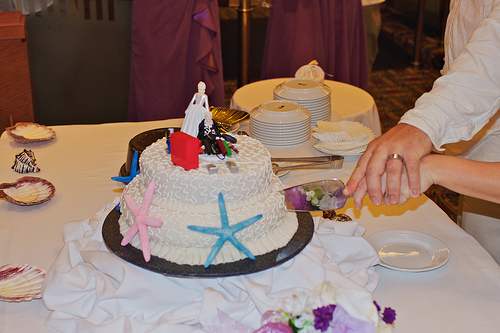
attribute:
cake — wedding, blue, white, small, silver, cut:
[111, 115, 290, 265]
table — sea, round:
[44, 114, 133, 224]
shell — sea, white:
[3, 170, 59, 228]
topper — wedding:
[178, 56, 234, 169]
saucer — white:
[250, 92, 323, 131]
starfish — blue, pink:
[191, 183, 264, 279]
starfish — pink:
[109, 172, 172, 258]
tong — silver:
[270, 147, 345, 176]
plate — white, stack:
[296, 81, 335, 99]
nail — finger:
[336, 187, 357, 203]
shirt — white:
[409, 23, 485, 81]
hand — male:
[380, 131, 420, 159]